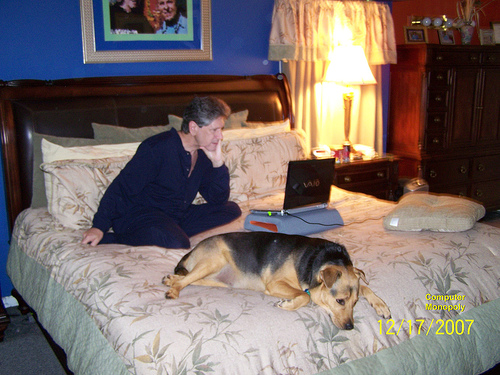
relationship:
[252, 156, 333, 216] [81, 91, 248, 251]
laptop in front of man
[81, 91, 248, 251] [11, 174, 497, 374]
lady on bed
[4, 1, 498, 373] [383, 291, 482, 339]
picture was taken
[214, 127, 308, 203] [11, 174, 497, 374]
pillow on bed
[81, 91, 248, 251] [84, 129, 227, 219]
woman in pajamas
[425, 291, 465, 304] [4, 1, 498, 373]
computer on photo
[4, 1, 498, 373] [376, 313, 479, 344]
photo has date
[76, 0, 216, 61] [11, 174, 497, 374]
picture above bed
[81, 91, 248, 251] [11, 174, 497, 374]
man on bed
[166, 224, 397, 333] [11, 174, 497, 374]
dog on bed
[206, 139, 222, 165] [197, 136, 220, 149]
hand on chin